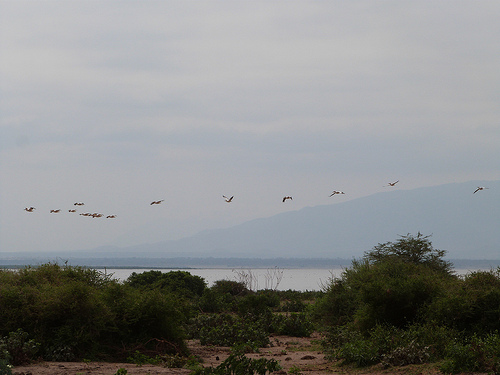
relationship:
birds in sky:
[116, 166, 385, 219] [174, 28, 364, 133]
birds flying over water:
[116, 166, 385, 219] [243, 263, 317, 299]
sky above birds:
[174, 28, 364, 133] [116, 166, 385, 219]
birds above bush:
[116, 166, 385, 219] [349, 245, 453, 321]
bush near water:
[349, 245, 453, 321] [243, 263, 317, 299]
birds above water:
[116, 166, 385, 219] [243, 263, 317, 299]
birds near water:
[116, 166, 385, 219] [243, 263, 317, 299]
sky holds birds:
[174, 28, 364, 133] [116, 166, 385, 219]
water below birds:
[243, 263, 317, 299] [116, 166, 385, 219]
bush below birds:
[349, 245, 453, 321] [116, 166, 385, 219]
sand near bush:
[266, 335, 308, 364] [349, 245, 453, 321]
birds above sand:
[116, 166, 385, 219] [266, 335, 308, 364]